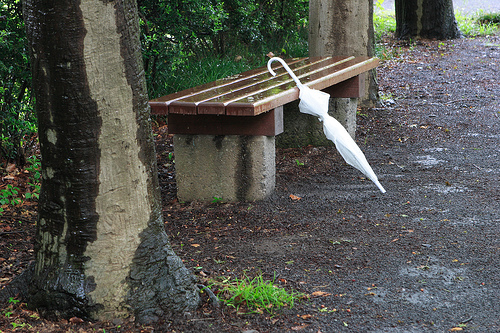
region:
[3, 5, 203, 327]
tree trunk with wet black marks on sides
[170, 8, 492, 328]
dark ground covered with soil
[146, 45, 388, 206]
white umbrella leaning on bench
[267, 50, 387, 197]
slanted umbrella closed tightly with strap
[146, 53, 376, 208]
bench of wooden boards above cement supports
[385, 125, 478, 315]
small puddles on ground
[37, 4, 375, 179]
green growth between tree trunks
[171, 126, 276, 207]
two short and one long wet mark on cement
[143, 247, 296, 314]
bright green blades of grass at tree base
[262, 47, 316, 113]
curved umbrella handle facing down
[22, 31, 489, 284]
this is in a park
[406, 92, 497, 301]
this is a walkway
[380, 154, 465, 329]
the ground here is wet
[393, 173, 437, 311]
the ground here is mud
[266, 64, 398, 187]
this is an umbrella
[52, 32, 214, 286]
the tree bark is brown and tan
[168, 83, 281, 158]
this is a bench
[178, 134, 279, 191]
the bench legs are stone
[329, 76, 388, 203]
the umbrella is white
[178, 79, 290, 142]
the bench is made of wood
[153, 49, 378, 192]
a wood bench with concrete base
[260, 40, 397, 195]
a white umbrella leaning on a bench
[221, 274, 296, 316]
a small patch of green grass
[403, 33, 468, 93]
brown leaves on the ground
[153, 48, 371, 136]
a wet wood bench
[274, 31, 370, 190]
a closed white umbrella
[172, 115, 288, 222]
a concrete base for a bench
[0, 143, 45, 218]
green weeds growing next to a tree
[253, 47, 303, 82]
a white umbrella handle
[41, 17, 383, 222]
two large trees next to a bench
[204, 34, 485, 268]
an umbrella on the ground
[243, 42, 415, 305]
an umbrella on the bench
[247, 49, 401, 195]
a white closed umbrella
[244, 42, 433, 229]
an umbrella that is white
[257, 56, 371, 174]
an umbrellas that is closed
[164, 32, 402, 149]
a bench that is outside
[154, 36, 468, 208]
a bench with an umbrella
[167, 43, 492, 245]
a bench with a white umbrella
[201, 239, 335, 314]
grass on the ground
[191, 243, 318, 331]
green grass on the ground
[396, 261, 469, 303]
wet, muddy spot on ground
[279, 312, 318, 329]
dried leaves on the ground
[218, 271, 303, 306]
patch of grass growing near tree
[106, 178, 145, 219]
dry spot on trunk of tree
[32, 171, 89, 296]
wet spot on trunk of tree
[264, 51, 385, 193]
white umbrella leaning on bench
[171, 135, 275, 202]
stone holding the bench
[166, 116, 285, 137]
wooden piece holding seat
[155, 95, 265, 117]
four wooden planks lined side by side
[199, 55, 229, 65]
wild grass growing behind bench